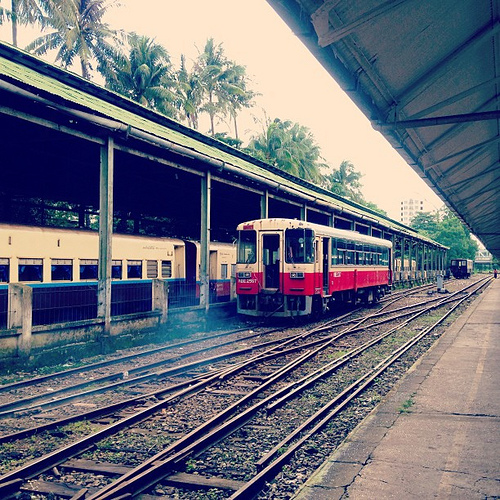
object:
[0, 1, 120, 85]
palm trees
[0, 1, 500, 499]
station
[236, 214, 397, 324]
trains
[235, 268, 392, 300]
pattern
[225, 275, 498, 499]
tracks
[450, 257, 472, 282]
car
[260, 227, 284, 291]
train door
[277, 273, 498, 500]
platform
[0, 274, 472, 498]
grass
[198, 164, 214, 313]
support beams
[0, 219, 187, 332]
train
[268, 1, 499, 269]
roofing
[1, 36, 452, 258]
roofing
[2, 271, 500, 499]
ground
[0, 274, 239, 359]
fence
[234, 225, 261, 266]
window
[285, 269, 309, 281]
light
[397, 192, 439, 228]
building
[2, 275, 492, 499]
gravel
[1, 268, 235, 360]
wood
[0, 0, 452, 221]
sky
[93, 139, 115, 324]
support beam